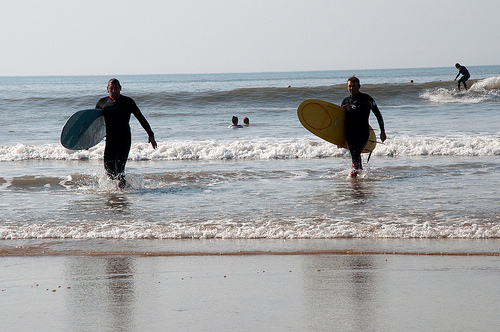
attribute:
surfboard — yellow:
[298, 99, 375, 152]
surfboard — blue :
[59, 107, 105, 149]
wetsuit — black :
[339, 92, 389, 169]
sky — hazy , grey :
[5, 5, 499, 98]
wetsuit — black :
[89, 96, 152, 186]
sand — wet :
[0, 234, 497, 326]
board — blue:
[56, 107, 106, 151]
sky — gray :
[248, 2, 415, 81]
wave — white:
[3, 133, 499, 159]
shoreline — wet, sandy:
[0, 236, 499, 331]